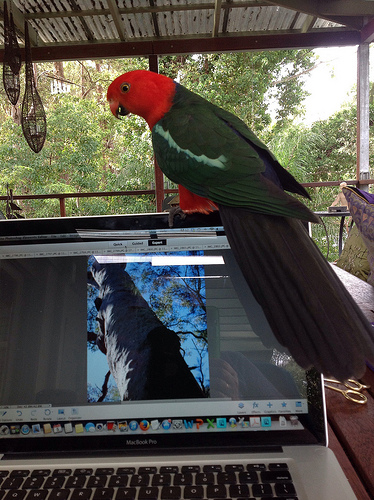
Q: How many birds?
A: One.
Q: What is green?
A: Tree.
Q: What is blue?
A: Sky.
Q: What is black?
A: Keyboard.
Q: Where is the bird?
A: On the computer.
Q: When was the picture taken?
A: Daytime.